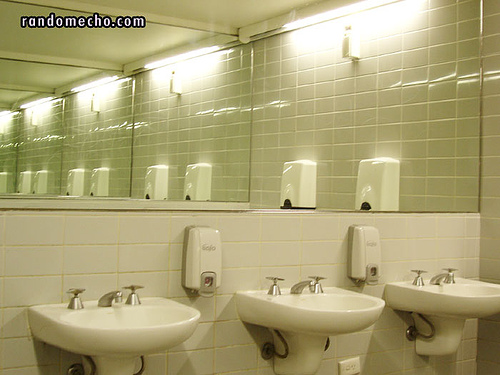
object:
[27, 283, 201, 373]
sink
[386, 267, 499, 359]
sink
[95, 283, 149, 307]
faucet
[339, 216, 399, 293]
dispenser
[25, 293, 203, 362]
sink bowl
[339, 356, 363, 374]
outlet plate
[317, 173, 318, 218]
ground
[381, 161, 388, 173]
ground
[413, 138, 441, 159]
ground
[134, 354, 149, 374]
tube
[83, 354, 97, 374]
tube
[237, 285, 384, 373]
sink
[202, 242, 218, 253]
logo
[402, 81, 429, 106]
tile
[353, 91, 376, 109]
tile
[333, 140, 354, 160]
tile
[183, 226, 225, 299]
soap dispenser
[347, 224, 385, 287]
soap dispenser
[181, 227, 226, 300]
dispenser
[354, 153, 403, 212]
soap dispensers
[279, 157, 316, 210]
soap dispensers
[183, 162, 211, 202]
soap dispensers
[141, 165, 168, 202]
soap dispensers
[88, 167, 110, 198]
soap dispensers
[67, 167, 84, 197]
soap dispensers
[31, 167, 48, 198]
soap dispensers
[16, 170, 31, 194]
soap dispensers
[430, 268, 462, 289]
faucet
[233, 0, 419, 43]
wall lights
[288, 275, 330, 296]
faucet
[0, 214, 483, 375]
wall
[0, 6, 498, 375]
bathroom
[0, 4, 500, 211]
reflection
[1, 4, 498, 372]
wall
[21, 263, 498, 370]
row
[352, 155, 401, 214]
dryer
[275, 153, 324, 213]
dryer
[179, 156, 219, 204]
dryer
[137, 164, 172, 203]
dryer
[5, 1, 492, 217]
mirror